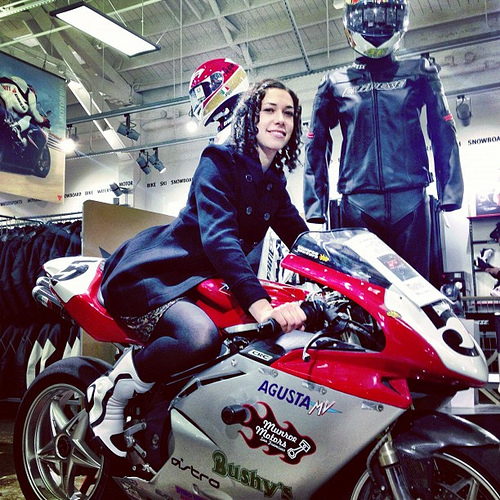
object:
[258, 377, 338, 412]
brand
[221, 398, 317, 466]
brand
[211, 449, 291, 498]
brand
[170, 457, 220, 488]
brand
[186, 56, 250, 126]
helmet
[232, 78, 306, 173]
hair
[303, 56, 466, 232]
motorcycle jacket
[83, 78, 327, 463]
girl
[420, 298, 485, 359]
5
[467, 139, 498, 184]
wall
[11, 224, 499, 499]
bike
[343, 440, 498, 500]
tire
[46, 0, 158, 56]
fixture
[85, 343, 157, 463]
boot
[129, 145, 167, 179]
light fixture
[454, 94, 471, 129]
light fixture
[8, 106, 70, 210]
wall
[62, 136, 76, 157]
light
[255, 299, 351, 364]
handlebar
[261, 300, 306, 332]
hand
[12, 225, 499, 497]
side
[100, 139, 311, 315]
coat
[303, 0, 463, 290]
outfit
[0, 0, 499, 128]
ceiling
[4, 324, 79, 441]
jackets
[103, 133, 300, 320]
jacket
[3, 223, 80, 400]
coats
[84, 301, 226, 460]
leg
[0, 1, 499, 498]
store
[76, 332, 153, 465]
foot